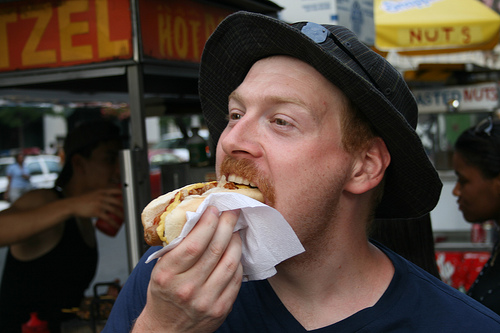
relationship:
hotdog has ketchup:
[138, 167, 284, 275] [129, 191, 196, 231]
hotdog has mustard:
[138, 167, 284, 275] [151, 191, 202, 240]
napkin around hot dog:
[140, 194, 307, 290] [127, 179, 262, 241]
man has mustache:
[183, 44, 400, 315] [220, 157, 272, 189]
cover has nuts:
[372, 0, 499, 54] [409, 25, 471, 45]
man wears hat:
[100, 10, 491, 333] [199, 11, 443, 213]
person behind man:
[448, 97, 499, 330] [100, 10, 491, 333]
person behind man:
[95, 8, 499, 330] [100, 10, 491, 333]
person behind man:
[0, 107, 147, 330] [100, 10, 491, 333]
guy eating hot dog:
[105, 8, 498, 330] [139, 181, 261, 243]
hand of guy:
[133, 204, 245, 331] [105, 8, 498, 330]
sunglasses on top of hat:
[291, 22, 374, 88] [199, 11, 443, 213]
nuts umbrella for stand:
[373, 0, 499, 50] [328, 1, 498, 166]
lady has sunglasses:
[0, 99, 152, 315] [470, 108, 498, 152]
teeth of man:
[221, 167, 251, 194] [100, 10, 491, 333]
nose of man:
[220, 113, 260, 161] [100, 10, 491, 333]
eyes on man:
[228, 104, 300, 134] [100, 10, 491, 333]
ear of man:
[344, 128, 393, 197] [100, 10, 491, 333]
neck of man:
[292, 206, 376, 303] [145, 30, 383, 317]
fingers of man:
[146, 207, 246, 319] [100, 10, 491, 333]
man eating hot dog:
[100, 10, 491, 333] [138, 180, 245, 245]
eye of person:
[269, 112, 298, 129] [95, 8, 499, 330]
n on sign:
[408, 26, 420, 42] [402, 26, 477, 43]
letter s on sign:
[460, 25, 473, 46] [373, 3, 495, 52]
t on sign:
[443, 23, 458, 43] [373, 3, 495, 52]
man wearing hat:
[100, 10, 491, 333] [196, 5, 452, 229]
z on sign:
[15, 9, 73, 76] [4, 0, 130, 65]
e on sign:
[58, 3, 91, 63] [0, 1, 154, 68]